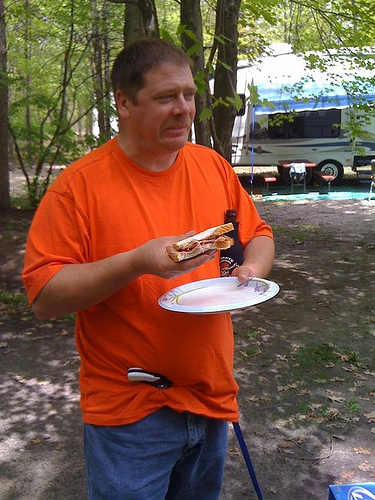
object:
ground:
[0, 165, 375, 499]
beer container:
[219, 209, 243, 277]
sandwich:
[166, 222, 235, 263]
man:
[22, 40, 275, 500]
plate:
[154, 239, 281, 326]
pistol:
[126, 367, 173, 389]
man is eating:
[22, 38, 275, 499]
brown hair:
[110, 38, 195, 107]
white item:
[121, 342, 184, 396]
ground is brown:
[363, 411, 374, 425]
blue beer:
[219, 209, 243, 277]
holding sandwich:
[137, 222, 235, 281]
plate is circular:
[157, 276, 281, 314]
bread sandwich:
[166, 223, 235, 263]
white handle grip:
[127, 367, 174, 389]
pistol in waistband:
[127, 367, 173, 389]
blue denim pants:
[83, 405, 228, 499]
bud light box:
[327, 482, 375, 499]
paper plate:
[157, 276, 280, 315]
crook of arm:
[217, 154, 275, 286]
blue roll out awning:
[249, 47, 373, 116]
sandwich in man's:
[166, 223, 234, 263]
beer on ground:
[328, 483, 374, 499]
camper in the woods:
[231, 44, 375, 166]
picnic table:
[261, 159, 335, 193]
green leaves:
[226, 95, 243, 113]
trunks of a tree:
[124, 0, 161, 47]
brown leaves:
[341, 354, 352, 361]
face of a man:
[130, 63, 196, 148]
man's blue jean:
[83, 405, 229, 499]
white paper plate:
[157, 276, 280, 314]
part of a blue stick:
[251, 103, 254, 180]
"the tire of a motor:
[313, 159, 344, 186]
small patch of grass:
[294, 334, 342, 372]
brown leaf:
[329, 396, 346, 404]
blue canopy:
[254, 82, 371, 116]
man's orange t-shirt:
[21, 135, 273, 426]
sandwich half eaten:
[166, 222, 235, 262]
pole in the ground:
[251, 107, 255, 194]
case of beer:
[327, 483, 375, 499]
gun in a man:
[127, 367, 173, 390]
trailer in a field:
[231, 43, 375, 187]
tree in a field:
[0, 0, 125, 211]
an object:
[233, 422, 265, 500]